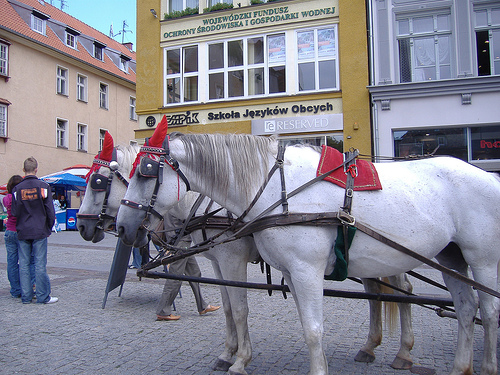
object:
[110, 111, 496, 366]
horse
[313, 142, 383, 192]
blanket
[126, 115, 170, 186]
tassel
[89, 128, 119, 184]
tassel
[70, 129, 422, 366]
horse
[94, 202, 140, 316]
sign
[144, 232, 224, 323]
man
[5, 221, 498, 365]
sidewalk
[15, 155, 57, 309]
man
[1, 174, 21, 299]
woman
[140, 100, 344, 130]
advertisement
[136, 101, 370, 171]
storefront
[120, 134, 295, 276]
bridle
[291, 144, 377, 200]
reins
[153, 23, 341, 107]
window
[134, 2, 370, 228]
building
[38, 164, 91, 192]
umbrella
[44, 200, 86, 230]
concessions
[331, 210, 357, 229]
buckle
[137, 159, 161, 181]
eye covering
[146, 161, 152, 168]
button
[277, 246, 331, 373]
leg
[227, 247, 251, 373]
leg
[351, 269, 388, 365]
leg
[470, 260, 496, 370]
leg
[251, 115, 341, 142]
sign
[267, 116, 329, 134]
letters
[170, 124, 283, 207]
mane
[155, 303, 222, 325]
shoes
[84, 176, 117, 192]
blinder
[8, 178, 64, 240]
jacket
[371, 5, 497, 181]
brick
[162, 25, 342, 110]
frame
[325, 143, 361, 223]
girth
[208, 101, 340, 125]
store name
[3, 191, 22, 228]
pink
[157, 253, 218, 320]
person